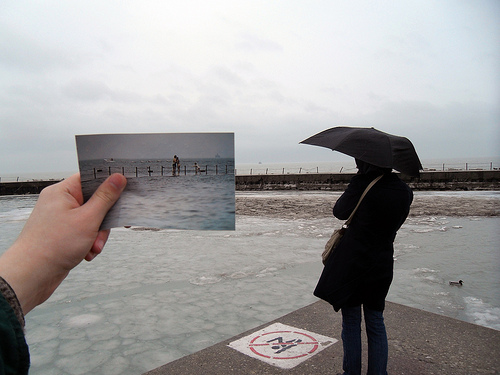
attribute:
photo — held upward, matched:
[50, 125, 235, 242]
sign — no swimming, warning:
[216, 309, 325, 359]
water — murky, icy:
[215, 163, 329, 245]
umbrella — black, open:
[328, 133, 431, 197]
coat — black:
[335, 151, 403, 326]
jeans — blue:
[310, 310, 429, 370]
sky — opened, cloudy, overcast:
[21, 18, 494, 103]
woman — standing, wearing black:
[322, 144, 401, 373]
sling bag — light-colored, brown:
[322, 172, 387, 258]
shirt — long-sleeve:
[342, 170, 407, 239]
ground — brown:
[192, 273, 499, 368]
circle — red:
[250, 308, 327, 374]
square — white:
[226, 312, 320, 361]